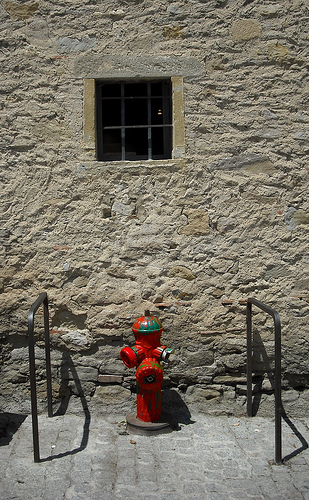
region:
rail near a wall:
[237, 293, 304, 475]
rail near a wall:
[16, 286, 61, 459]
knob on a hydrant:
[117, 337, 133, 364]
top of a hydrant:
[133, 304, 157, 330]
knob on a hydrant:
[134, 363, 168, 391]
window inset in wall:
[87, 76, 170, 160]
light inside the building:
[155, 100, 164, 121]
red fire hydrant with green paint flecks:
[123, 306, 171, 416]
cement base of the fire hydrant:
[126, 414, 171, 433]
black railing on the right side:
[244, 296, 285, 468]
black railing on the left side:
[21, 289, 63, 455]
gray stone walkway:
[1, 411, 306, 498]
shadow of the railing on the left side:
[41, 350, 94, 461]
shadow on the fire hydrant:
[140, 388, 166, 420]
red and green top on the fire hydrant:
[131, 314, 157, 330]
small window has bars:
[94, 76, 176, 164]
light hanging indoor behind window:
[156, 106, 160, 116]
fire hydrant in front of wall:
[118, 306, 180, 437]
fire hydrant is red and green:
[119, 306, 176, 434]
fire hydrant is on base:
[124, 404, 176, 437]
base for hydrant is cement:
[122, 407, 175, 439]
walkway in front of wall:
[0, 407, 307, 498]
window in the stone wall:
[74, 53, 181, 166]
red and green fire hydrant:
[114, 305, 179, 431]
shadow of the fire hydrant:
[161, 382, 198, 433]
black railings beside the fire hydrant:
[26, 287, 289, 461]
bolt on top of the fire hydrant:
[144, 306, 149, 313]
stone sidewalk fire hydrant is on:
[1, 414, 308, 497]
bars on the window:
[99, 84, 166, 160]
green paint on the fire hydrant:
[130, 321, 158, 366]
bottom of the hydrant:
[121, 396, 182, 442]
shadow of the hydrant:
[162, 384, 200, 445]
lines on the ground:
[111, 435, 211, 483]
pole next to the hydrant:
[221, 279, 299, 348]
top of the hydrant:
[121, 304, 173, 340]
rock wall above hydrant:
[101, 199, 210, 271]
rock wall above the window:
[69, 7, 180, 52]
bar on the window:
[136, 83, 162, 150]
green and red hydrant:
[110, 300, 194, 413]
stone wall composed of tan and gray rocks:
[2, 0, 300, 407]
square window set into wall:
[60, 49, 204, 174]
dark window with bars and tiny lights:
[91, 75, 174, 163]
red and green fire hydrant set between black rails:
[24, 282, 283, 462]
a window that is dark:
[91, 88, 170, 165]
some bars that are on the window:
[101, 78, 175, 159]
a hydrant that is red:
[119, 271, 192, 446]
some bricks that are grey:
[120, 454, 188, 491]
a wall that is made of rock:
[7, 193, 264, 321]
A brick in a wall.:
[216, 374, 257, 389]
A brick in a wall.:
[96, 375, 126, 382]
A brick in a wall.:
[94, 386, 129, 398]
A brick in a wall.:
[67, 382, 92, 394]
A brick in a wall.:
[56, 367, 91, 380]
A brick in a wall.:
[176, 383, 187, 387]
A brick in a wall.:
[99, 373, 125, 381]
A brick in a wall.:
[213, 373, 248, 379]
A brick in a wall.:
[235, 385, 257, 394]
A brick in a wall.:
[63, 373, 97, 381]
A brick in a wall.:
[166, 373, 197, 380]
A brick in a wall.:
[8, 375, 29, 382]